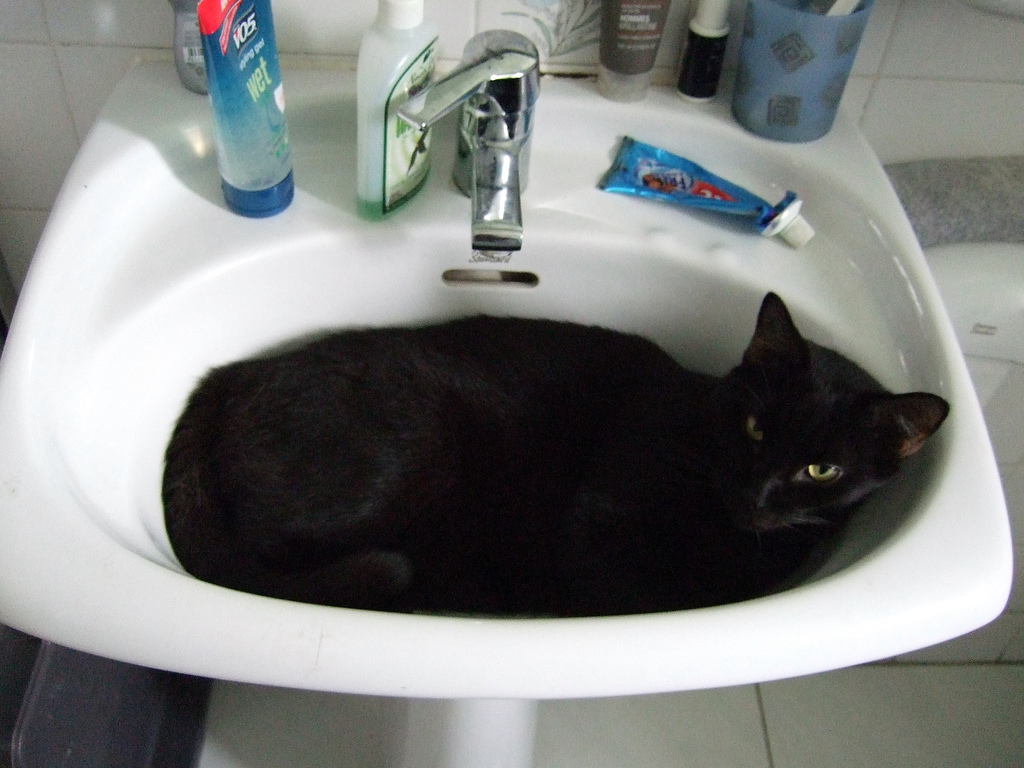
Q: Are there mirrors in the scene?
A: No, there are no mirrors.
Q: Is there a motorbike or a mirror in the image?
A: No, there are no mirrors or motorcycles.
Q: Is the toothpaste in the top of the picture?
A: Yes, the toothpaste is in the top of the image.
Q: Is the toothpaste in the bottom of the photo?
A: No, the toothpaste is in the top of the image.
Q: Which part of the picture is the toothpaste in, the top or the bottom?
A: The toothpaste is in the top of the image.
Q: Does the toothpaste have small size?
A: Yes, the toothpaste is small.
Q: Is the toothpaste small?
A: Yes, the toothpaste is small.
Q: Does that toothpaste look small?
A: Yes, the toothpaste is small.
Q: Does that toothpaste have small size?
A: Yes, the toothpaste is small.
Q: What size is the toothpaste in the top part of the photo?
A: The toothpaste is small.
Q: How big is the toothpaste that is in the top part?
A: The toothpaste is small.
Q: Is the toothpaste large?
A: No, the toothpaste is small.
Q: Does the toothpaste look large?
A: No, the toothpaste is small.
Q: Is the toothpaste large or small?
A: The toothpaste is small.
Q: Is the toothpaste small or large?
A: The toothpaste is small.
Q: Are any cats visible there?
A: Yes, there is a cat.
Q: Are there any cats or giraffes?
A: Yes, there is a cat.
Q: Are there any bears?
A: No, there are no bears.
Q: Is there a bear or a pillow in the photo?
A: No, there are no bears or pillows.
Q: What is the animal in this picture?
A: The animal is a cat.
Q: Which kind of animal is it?
A: The animal is a cat.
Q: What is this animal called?
A: This is a cat.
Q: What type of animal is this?
A: This is a cat.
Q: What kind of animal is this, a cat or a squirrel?
A: This is a cat.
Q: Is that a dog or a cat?
A: That is a cat.